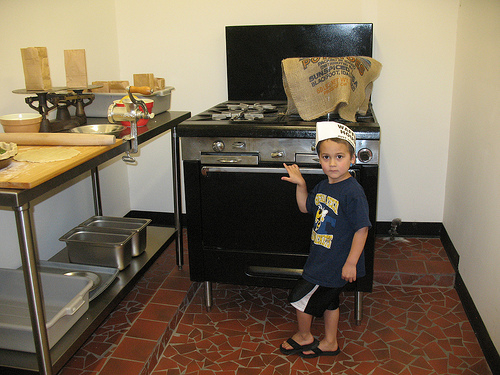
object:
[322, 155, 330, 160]
eye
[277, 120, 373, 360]
boy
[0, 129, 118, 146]
dough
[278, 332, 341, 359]
flip flops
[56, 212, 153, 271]
pots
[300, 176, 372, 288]
shirt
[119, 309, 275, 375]
floor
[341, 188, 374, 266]
arm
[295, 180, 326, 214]
arm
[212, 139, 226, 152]
knob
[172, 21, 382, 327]
oven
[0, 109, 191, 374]
table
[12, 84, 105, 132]
metal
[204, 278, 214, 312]
metal pie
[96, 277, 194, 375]
step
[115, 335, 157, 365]
stone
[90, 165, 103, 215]
leg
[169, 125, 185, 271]
leg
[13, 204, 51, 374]
leg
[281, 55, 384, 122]
sack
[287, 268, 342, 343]
legs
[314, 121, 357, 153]
hat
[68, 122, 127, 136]
pan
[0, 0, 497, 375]
kitchen